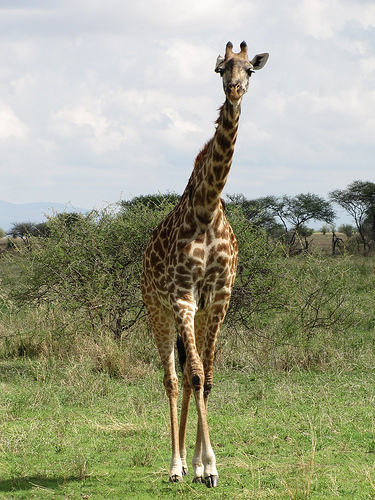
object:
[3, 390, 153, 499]
grass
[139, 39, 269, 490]
giraffe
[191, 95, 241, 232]
neck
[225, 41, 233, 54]
antlers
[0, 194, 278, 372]
trees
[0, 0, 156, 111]
clouds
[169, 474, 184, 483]
hooves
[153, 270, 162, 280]
spots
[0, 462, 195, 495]
shadow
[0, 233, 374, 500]
ground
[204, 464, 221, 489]
feet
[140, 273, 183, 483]
legs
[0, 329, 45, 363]
weeds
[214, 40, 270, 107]
head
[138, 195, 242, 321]
body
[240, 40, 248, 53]
horns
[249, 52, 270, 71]
ear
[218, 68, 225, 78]
eyes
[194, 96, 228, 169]
hair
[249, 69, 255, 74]
eyelashes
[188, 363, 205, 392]
knees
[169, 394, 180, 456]
shins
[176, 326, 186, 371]
tail